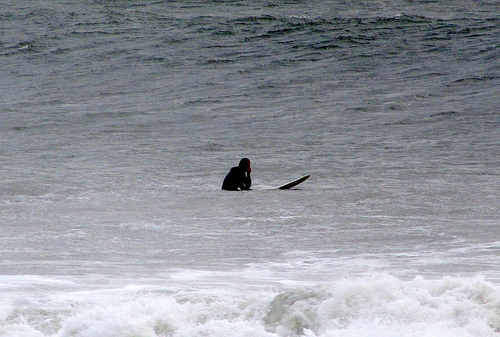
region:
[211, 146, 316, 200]
A surfer waiting for a wave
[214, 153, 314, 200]
A surfer waiting for a wave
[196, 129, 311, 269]
a man is in water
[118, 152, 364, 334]
view is in the ovean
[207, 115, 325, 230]
man is on a sufingboard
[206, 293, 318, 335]
part of the water waves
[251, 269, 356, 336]
waves are wgite in color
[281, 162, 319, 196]
surfboard is white in color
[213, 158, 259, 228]
man is dressed in black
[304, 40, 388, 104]
the water is still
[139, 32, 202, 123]
water is colorles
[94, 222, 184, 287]
pat of the calm water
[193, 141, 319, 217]
Person on surfboard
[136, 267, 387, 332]
white waves crashing onto beach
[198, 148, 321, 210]
person relaxing on surfboard while in water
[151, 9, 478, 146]
High waves in ocean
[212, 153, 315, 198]
surfer on surfboard waiting for nex wave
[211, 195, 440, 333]
White waves meeting the shore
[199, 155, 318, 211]
Surfer thinking on surfboard in water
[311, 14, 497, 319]
Dark gray water meeting the shore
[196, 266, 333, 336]
White and foamy ocean wave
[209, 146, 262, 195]
Person with chin in their hand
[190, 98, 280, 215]
a man in the water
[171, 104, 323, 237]
a man in the sea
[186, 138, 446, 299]
a man in the ocean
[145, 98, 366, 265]
a man in the beach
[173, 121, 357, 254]
a man in the boat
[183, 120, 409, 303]
a man in the board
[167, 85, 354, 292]
a man in the skate board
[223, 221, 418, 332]
a flow of water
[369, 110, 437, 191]
riddles in the water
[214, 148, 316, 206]
SURFER ON BOARD IN OCEAN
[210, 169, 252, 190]
BLACK WET SUIT ON SURFER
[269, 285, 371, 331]
WHITE WATER OF WAVES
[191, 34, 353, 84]
DARK GREEN WATER IN OCEAN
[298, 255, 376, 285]
WATER SPRAYING UP IN AIR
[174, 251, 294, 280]
WHITE FOAM IN SEA WATER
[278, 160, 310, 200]
BOARD STICKING UP OUT OF WATER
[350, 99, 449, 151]
SMALL WAVES NEAR SURFER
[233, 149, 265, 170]
DARK HAIR OF SURFER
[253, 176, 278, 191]
WHITE FOAM NEAR SURFER